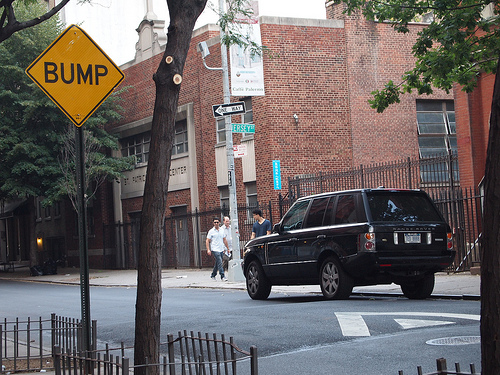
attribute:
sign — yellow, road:
[21, 20, 128, 130]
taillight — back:
[357, 231, 377, 252]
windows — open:
[416, 110, 449, 140]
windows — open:
[416, 134, 447, 159]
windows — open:
[414, 160, 452, 186]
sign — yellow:
[215, 105, 242, 112]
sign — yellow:
[225, 122, 258, 132]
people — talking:
[198, 203, 249, 292]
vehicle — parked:
[241, 188, 456, 301]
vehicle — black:
[209, 153, 471, 315]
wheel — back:
[313, 259, 360, 305]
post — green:
[30, 26, 139, 373]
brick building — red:
[4, 0, 499, 272]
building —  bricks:
[162, 0, 498, 217]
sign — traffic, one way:
[210, 99, 245, 118]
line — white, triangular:
[393, 315, 456, 332]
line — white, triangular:
[331, 309, 481, 339]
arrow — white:
[214, 101, 244, 117]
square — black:
[208, 100, 245, 118]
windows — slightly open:
[417, 107, 461, 179]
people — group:
[191, 203, 246, 282]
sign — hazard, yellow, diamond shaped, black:
[25, 24, 126, 127]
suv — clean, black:
[237, 185, 453, 299]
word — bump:
[38, 61, 115, 87]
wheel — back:
[395, 268, 444, 298]